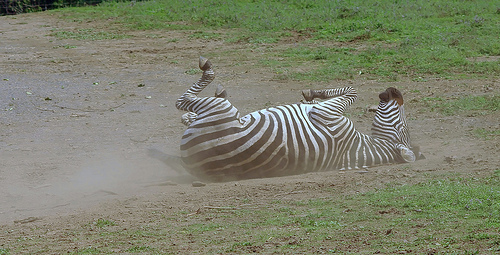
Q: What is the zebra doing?
A: Rolling in the dirt.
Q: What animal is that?
A: Zebra.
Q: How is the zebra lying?
A: On its back.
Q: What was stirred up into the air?
A: Dirt.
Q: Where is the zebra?
A: Grass and dirt field.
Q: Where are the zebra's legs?
A: Off the gound into the air.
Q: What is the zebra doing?
A: Rolling on its back.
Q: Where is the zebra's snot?
A: Pointed towards the sky.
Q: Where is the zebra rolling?
A: Dirt.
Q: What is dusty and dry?
A: The dirt.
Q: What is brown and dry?
A: Dirt.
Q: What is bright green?
A: Grass.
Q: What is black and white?
A: Zebra.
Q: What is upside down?
A: The zebra.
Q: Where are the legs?
A: In the air.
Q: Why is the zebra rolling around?
A: Scratching his back.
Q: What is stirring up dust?
A: Zebra.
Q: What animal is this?
A: Zebra.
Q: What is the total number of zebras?
A: 1.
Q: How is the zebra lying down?
A: On its back.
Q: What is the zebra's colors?
A: Black and white.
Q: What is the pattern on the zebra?
A: Stripes.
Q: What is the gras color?
A: Green.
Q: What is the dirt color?
A: Brown.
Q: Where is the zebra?
A: On the ground.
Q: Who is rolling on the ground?
A: The zebra.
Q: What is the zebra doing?
A: Rolling.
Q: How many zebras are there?
A: One.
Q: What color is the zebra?
A: White and black.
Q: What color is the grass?
A: Green.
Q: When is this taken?
A: During the day.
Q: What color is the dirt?
A: Brown.